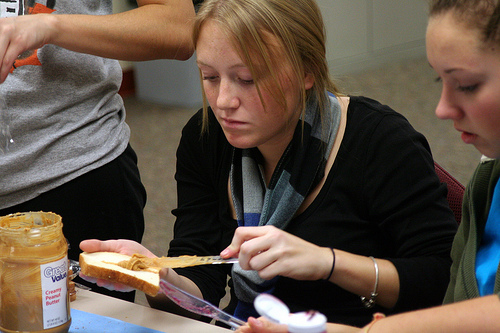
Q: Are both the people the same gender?
A: Yes, all the people are female.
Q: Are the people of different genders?
A: No, all the people are female.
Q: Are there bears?
A: No, there are no bears.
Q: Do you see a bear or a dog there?
A: No, there are no bears or dogs.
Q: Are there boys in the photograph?
A: No, there are no boys.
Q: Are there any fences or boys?
A: No, there are no boys or fences.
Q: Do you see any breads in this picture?
A: Yes, there is a bread.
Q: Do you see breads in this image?
A: Yes, there is a bread.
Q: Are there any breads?
A: Yes, there is a bread.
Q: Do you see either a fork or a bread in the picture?
A: Yes, there is a bread.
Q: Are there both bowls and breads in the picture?
A: No, there is a bread but no bowls.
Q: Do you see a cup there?
A: No, there are no cups.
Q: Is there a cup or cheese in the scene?
A: No, there are no cups or cheese.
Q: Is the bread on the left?
A: Yes, the bread is on the left of the image.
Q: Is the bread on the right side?
A: No, the bread is on the left of the image.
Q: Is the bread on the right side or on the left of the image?
A: The bread is on the left of the image.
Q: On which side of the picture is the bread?
A: The bread is on the left of the image.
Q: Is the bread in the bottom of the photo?
A: Yes, the bread is in the bottom of the image.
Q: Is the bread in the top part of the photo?
A: No, the bread is in the bottom of the image.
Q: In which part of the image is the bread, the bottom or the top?
A: The bread is in the bottom of the image.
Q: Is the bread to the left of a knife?
A: Yes, the bread is to the left of a knife.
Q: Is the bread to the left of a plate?
A: No, the bread is to the left of a knife.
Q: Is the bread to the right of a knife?
A: No, the bread is to the left of a knife.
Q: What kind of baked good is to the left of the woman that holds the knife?
A: The food is a bread.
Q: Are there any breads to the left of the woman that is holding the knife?
A: Yes, there is a bread to the left of the woman.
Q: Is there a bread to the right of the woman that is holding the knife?
A: No, the bread is to the left of the woman.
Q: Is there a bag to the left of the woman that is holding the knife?
A: No, there is a bread to the left of the woman.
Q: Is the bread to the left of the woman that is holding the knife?
A: Yes, the bread is to the left of the woman.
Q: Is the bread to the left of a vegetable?
A: No, the bread is to the left of the woman.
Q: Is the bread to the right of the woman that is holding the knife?
A: No, the bread is to the left of the woman.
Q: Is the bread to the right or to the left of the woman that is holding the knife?
A: The bread is to the left of the woman.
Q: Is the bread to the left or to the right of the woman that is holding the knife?
A: The bread is to the left of the woman.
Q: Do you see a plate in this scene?
A: No, there are no plates.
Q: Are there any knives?
A: Yes, there is a knife.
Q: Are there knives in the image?
A: Yes, there is a knife.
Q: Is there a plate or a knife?
A: Yes, there is a knife.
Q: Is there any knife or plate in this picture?
A: Yes, there is a knife.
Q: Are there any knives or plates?
A: Yes, there is a knife.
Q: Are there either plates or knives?
A: Yes, there is a knife.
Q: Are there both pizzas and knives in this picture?
A: No, there is a knife but no pizzas.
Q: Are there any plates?
A: No, there are no plates.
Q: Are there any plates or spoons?
A: No, there are no plates or spoons.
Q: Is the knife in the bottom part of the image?
A: Yes, the knife is in the bottom of the image.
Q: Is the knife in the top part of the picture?
A: No, the knife is in the bottom of the image.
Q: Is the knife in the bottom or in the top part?
A: The knife is in the bottom of the image.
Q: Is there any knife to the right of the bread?
A: Yes, there is a knife to the right of the bread.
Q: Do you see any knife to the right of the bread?
A: Yes, there is a knife to the right of the bread.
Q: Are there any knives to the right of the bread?
A: Yes, there is a knife to the right of the bread.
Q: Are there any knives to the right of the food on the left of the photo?
A: Yes, there is a knife to the right of the bread.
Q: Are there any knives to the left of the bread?
A: No, the knife is to the right of the bread.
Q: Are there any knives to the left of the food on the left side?
A: No, the knife is to the right of the bread.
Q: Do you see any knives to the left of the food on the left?
A: No, the knife is to the right of the bread.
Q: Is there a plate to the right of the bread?
A: No, there is a knife to the right of the bread.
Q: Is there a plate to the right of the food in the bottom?
A: No, there is a knife to the right of the bread.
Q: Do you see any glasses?
A: No, there are no glasses.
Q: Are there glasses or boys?
A: No, there are no glasses or boys.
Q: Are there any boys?
A: No, there are no boys.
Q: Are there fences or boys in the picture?
A: No, there are no boys or fences.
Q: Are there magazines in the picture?
A: No, there are no magazines.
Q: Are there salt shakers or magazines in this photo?
A: No, there are no magazines or salt shakers.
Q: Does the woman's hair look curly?
A: Yes, the hair is curly.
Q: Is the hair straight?
A: No, the hair is curly.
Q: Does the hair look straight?
A: No, the hair is curly.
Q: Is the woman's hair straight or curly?
A: The hair is curly.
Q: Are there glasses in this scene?
A: No, there are no glasses.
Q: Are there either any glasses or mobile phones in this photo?
A: No, there are no glasses or mobile phones.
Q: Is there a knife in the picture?
A: Yes, there is a knife.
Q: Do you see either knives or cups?
A: Yes, there is a knife.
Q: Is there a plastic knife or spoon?
A: Yes, there is a plastic knife.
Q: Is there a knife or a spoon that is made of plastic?
A: Yes, the knife is made of plastic.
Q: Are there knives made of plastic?
A: Yes, there is a knife that is made of plastic.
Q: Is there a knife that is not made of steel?
A: Yes, there is a knife that is made of plastic.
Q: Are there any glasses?
A: No, there are no glasses.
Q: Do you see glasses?
A: No, there are no glasses.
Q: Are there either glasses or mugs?
A: No, there are no glasses or mugs.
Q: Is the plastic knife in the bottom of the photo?
A: Yes, the knife is in the bottom of the image.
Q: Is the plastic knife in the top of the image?
A: No, the knife is in the bottom of the image.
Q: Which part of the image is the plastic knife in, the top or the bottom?
A: The knife is in the bottom of the image.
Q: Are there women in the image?
A: Yes, there is a woman.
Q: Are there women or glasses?
A: Yes, there is a woman.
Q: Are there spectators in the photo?
A: No, there are no spectators.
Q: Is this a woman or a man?
A: This is a woman.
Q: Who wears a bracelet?
A: The woman wears a bracelet.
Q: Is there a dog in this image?
A: No, there are no dogs.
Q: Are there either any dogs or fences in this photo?
A: No, there are no dogs or fences.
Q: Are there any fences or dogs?
A: No, there are no dogs or fences.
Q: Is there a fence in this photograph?
A: No, there are no fences.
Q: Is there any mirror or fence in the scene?
A: No, there are no fences or mirrors.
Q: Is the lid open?
A: Yes, the lid is open.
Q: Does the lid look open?
A: Yes, the lid is open.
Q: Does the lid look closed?
A: No, the lid is open.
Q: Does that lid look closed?
A: No, the lid is open.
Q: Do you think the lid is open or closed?
A: The lid is open.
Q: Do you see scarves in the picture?
A: Yes, there is a scarf.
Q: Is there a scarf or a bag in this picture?
A: Yes, there is a scarf.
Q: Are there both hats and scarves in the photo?
A: No, there is a scarf but no hats.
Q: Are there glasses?
A: No, there are no glasses.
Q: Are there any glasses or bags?
A: No, there are no glasses or bags.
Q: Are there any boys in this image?
A: No, there are no boys.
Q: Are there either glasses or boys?
A: No, there are no boys or glasses.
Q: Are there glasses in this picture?
A: No, there are no glasses.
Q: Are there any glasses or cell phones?
A: No, there are no glasses or cell phones.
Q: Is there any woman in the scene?
A: Yes, there is a woman.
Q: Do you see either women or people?
A: Yes, there is a woman.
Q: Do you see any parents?
A: No, there are no parents.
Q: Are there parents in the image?
A: No, there are no parents.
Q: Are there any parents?
A: No, there are no parents.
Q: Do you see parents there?
A: No, there are no parents.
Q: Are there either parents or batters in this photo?
A: No, there are no parents or batters.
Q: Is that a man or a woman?
A: That is a woman.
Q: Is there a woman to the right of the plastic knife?
A: Yes, there is a woman to the right of the knife.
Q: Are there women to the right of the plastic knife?
A: Yes, there is a woman to the right of the knife.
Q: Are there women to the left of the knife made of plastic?
A: No, the woman is to the right of the knife.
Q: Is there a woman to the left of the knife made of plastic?
A: No, the woman is to the right of the knife.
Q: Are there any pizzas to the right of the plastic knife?
A: No, there is a woman to the right of the knife.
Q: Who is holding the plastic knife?
A: The woman is holding the knife.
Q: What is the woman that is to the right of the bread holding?
A: The woman is holding the knife.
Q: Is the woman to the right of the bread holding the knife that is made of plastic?
A: Yes, the woman is holding the knife.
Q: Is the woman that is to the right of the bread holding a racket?
A: No, the woman is holding the knife.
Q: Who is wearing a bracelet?
A: The woman is wearing a bracelet.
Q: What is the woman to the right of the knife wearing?
A: The woman is wearing a bracelet.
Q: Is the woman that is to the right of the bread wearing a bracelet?
A: Yes, the woman is wearing a bracelet.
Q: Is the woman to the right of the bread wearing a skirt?
A: No, the woman is wearing a bracelet.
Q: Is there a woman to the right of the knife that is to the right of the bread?
A: Yes, there is a woman to the right of the knife.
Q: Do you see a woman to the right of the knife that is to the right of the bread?
A: Yes, there is a woman to the right of the knife.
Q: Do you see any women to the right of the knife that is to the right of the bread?
A: Yes, there is a woman to the right of the knife.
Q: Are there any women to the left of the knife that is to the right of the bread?
A: No, the woman is to the right of the knife.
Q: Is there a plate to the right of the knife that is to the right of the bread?
A: No, there is a woman to the right of the knife.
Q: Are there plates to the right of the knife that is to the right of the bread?
A: No, there is a woman to the right of the knife.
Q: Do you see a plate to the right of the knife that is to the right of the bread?
A: No, there is a woman to the right of the knife.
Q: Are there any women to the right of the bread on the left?
A: Yes, there is a woman to the right of the bread.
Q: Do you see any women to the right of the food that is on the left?
A: Yes, there is a woman to the right of the bread.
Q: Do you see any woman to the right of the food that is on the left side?
A: Yes, there is a woman to the right of the bread.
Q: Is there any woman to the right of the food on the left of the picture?
A: Yes, there is a woman to the right of the bread.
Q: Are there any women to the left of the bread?
A: No, the woman is to the right of the bread.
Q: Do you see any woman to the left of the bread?
A: No, the woman is to the right of the bread.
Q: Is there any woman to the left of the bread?
A: No, the woman is to the right of the bread.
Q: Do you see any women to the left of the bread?
A: No, the woman is to the right of the bread.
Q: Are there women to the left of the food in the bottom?
A: No, the woman is to the right of the bread.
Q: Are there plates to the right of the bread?
A: No, there is a woman to the right of the bread.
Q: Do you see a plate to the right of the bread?
A: No, there is a woman to the right of the bread.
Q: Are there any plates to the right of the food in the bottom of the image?
A: No, there is a woman to the right of the bread.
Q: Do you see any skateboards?
A: No, there are no skateboards.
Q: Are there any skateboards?
A: No, there are no skateboards.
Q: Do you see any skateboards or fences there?
A: No, there are no skateboards or fences.